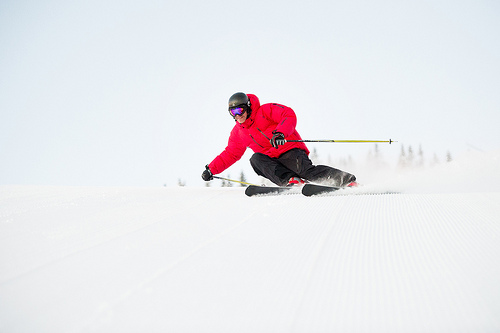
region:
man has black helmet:
[224, 91, 256, 108]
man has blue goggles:
[218, 106, 253, 123]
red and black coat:
[226, 88, 316, 156]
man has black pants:
[224, 148, 344, 189]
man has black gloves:
[256, 117, 303, 156]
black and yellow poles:
[280, 116, 405, 148]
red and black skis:
[299, 179, 361, 207]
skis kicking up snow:
[307, 182, 419, 192]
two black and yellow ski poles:
[212, 138, 394, 185]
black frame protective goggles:
[227, 105, 248, 118]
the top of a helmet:
[228, 92, 248, 104]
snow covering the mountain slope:
[3, 205, 496, 329]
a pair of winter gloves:
[200, 130, 286, 182]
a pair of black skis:
[242, 181, 409, 197]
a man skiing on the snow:
[10, 90, 497, 272]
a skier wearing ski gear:
[200, 90, 408, 197]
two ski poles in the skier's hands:
[200, 138, 397, 186]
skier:
[185, 76, 375, 204]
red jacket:
[222, 88, 297, 162]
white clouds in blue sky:
[402, 61, 427, 81]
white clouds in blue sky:
[372, 33, 446, 85]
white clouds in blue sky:
[324, 42, 381, 73]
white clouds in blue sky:
[97, 22, 151, 52]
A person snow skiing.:
[201, 84, 373, 207]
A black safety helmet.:
[224, 88, 254, 125]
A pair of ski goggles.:
[225, 97, 251, 117]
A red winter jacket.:
[210, 95, 305, 170]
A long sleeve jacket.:
[206, 96, 306, 166]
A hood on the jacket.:
[240, 81, 260, 116]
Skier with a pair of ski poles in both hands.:
[210, 130, 395, 185]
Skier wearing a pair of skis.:
[195, 90, 355, 195]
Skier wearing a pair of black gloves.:
[196, 86, 356, 196]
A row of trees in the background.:
[165, 131, 463, 188]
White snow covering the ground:
[68, 283, 106, 322]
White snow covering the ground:
[165, 208, 206, 251]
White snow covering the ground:
[175, 258, 207, 300]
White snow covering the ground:
[215, 194, 292, 265]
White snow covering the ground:
[283, 258, 342, 321]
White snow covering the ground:
[373, 207, 482, 328]